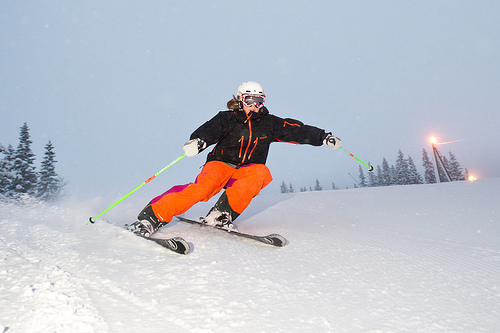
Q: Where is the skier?
A: Mountain.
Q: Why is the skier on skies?
A: To ski.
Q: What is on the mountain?
A: Snow.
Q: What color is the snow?
A: White.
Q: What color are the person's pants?
A: Orange and pink.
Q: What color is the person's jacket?
A: Black.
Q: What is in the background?
A: Trees.